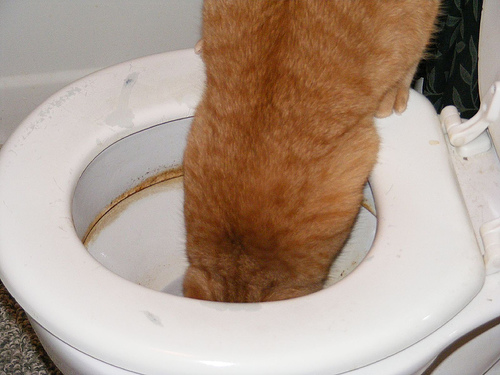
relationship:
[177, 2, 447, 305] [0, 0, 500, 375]
cat in room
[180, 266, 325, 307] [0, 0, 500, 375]
head in room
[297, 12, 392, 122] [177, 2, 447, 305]
striped orange cat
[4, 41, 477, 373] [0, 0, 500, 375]
seat on room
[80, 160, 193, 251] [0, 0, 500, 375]
stain in room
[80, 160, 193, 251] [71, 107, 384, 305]
stain in toilet bowl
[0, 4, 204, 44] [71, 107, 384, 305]
side of toilet bowl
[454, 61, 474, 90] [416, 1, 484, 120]
leaves on curtain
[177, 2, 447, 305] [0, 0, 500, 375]
cat on room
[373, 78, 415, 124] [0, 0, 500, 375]
foot on room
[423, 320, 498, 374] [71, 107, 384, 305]
outside of toilet bowl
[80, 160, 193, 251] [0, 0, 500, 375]
ring inside of room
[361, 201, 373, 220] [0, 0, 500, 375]
ring inside of room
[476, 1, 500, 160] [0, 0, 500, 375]
lid on room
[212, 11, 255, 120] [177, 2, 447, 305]
stripes in cats fur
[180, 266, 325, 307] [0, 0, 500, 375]
head inside of room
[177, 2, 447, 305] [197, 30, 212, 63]
cat has orange paw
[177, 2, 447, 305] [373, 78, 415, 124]
cat has orange paw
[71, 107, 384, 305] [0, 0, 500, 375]
toilet bowl in room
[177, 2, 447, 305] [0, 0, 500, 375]
cat down into room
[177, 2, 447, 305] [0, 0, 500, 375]
tabby reaching room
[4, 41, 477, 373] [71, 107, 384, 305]
seat on bowl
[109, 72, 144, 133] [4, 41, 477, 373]
scoff on seat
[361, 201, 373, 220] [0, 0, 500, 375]
ring around room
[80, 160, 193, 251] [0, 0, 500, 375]
ring around room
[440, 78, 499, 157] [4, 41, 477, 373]
hinge on seat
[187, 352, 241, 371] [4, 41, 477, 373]
light reflecting off seat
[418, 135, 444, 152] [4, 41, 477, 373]
dirt on seat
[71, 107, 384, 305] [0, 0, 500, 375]
toilet bowl next to room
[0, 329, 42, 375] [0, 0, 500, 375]
floor under room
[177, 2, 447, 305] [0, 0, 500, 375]
kitty drinking out of room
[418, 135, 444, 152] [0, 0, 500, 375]
dirt along room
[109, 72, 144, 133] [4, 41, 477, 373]
peeling toilet seat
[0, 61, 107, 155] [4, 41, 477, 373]
molding toilet seat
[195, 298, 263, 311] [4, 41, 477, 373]
peeling toilet seat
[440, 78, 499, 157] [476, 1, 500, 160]
hinge hold lid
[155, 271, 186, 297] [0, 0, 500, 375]
water in room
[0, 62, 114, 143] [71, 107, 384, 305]
molding along toilet bowl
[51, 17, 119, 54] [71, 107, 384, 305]
white paint on toilet bowl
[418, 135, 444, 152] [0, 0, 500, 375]
dirt on room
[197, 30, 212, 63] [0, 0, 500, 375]
paw on room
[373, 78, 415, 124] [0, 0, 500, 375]
paw on room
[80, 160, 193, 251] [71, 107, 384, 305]
brown line around toilet bowl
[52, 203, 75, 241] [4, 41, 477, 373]
mark on seat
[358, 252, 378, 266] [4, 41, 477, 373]
mark on seat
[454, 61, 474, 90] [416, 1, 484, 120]
leaves on a background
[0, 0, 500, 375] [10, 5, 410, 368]
room in room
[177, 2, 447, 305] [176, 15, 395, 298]
fur of cat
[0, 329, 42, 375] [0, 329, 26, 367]
floor on floor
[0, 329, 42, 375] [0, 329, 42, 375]
floor on floor